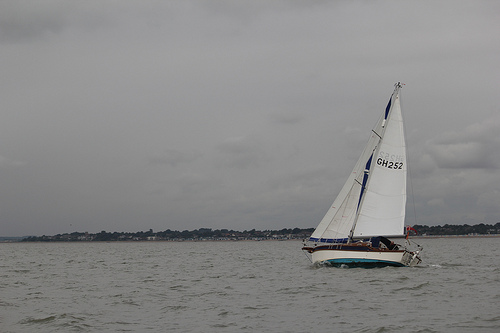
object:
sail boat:
[300, 79, 425, 270]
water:
[0, 236, 499, 331]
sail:
[309, 80, 408, 241]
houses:
[147, 236, 156, 241]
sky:
[1, 1, 500, 236]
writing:
[375, 157, 404, 170]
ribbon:
[403, 224, 419, 240]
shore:
[0, 234, 499, 245]